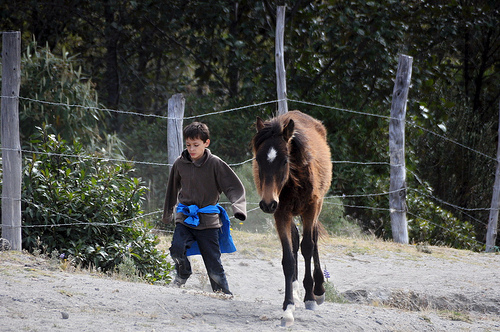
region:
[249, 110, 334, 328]
Horse running on the dirt field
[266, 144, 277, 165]
White spot on the forehead of the horse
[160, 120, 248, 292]
Boy running on the field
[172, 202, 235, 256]
A coat tied on the boy's waist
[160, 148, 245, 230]
Hoodie on the boy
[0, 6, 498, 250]
Wood sticks around the field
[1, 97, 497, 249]
Wires on the sticks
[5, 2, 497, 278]
Trees outside of the wires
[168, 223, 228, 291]
Pants on the boy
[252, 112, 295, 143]
Horse's ears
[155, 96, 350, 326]
A boy and an animal.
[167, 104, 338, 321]
Boy walking beside a horse.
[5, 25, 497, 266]
A wire fence behind the horse.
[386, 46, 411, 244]
Wooden fence post.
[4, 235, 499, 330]
Field with dirt and grass.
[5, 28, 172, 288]
Green bush behind a fence.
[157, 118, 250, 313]
Young boy with a blue jacket.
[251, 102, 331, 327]
Horse walking in a pasture.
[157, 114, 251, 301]
Boy wearing blue jeans.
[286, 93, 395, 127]
Wire on a fence.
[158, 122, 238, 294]
this is a boy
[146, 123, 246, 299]
the boy is walking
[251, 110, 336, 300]
this is a horse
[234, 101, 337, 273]
the horse is behind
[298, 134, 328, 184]
the horse is brown in color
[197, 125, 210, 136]
the hair is black in color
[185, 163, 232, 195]
this is the jacket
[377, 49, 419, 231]
this is a pole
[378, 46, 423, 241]
the pole is big in size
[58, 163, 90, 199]
the leaves are green in color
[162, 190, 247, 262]
boy with jacket tied around waist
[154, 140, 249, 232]
boy wearing olive green shirt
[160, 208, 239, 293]
person wearing blue jeans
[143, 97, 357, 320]
boy running next to horse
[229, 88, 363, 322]
horse has brown coat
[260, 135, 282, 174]
horse has white mark on head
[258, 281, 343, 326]
horse has white feet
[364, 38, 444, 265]
wooden fence post in ground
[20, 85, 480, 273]
grey wire fence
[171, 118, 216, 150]
boy has dark brown hair